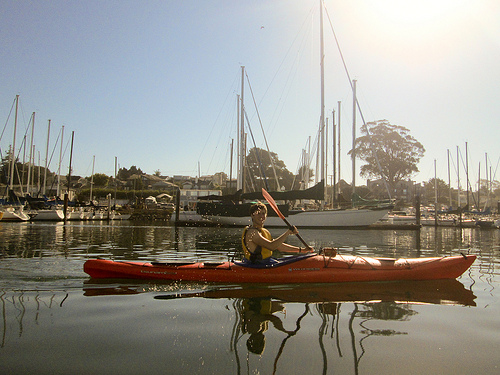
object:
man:
[236, 201, 316, 266]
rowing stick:
[260, 182, 314, 254]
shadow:
[154, 277, 480, 372]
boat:
[84, 250, 480, 284]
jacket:
[240, 225, 276, 262]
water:
[2, 210, 499, 374]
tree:
[356, 112, 425, 229]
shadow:
[352, 287, 425, 338]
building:
[167, 183, 225, 199]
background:
[1, 6, 500, 230]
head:
[252, 201, 267, 225]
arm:
[249, 227, 295, 253]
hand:
[284, 226, 305, 239]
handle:
[283, 217, 312, 249]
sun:
[306, 5, 500, 71]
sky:
[1, 2, 500, 190]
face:
[254, 207, 266, 225]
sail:
[202, 182, 328, 205]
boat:
[170, 197, 400, 232]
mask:
[186, 194, 292, 219]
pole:
[317, 5, 325, 214]